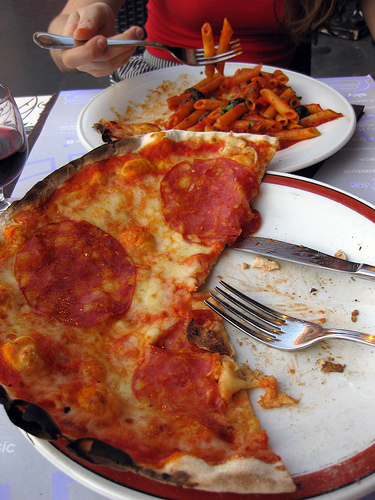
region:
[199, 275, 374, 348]
silver fork by the pizza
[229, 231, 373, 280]
silver knife by the pizza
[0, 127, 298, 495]
pepperoni pizza on the plate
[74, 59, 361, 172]
white plate with pasta on it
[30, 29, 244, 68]
silver fork with pasta on it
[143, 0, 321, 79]
red shirt on the woman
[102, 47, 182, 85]
black and white stripe bottoms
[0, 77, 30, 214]
clear glass of red wine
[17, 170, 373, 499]
red, white and black plate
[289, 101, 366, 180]
black napkin under the white plate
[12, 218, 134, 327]
pepperoni on pizza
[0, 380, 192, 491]
burnt pizza crust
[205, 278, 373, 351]
metal fork on the plate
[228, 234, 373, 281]
metal knife on the plate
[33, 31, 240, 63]
metal fork in woman's hand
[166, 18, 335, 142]
pasta dish on the plate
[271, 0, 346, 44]
woman's brown hair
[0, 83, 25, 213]
red wine in wine glass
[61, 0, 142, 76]
woman's hand holding the fork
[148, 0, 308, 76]
woman wearing a red shirt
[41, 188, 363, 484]
Pizza on a plate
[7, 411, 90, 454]
The crust on the pizza is burnt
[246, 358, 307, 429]
Piece of cheese on the plate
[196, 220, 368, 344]
Fork and knife on the plate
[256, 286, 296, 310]
Sauce on the plate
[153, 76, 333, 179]
Pasta in a bowl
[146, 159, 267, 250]
Pepperoni on top of pizza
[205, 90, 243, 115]
Spices on top of pasta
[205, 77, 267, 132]
Round noodles on plate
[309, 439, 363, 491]
The plate is round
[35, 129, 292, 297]
A partially eaten pizza.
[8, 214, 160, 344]
Pizza with many pepparoni's.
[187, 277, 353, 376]
A silver fork on the plate.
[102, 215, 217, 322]
Mega cheese on the pizza.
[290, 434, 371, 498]
A white plate with a burgandy rim.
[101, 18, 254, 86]
Forking up pasta with sauce.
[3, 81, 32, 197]
Glass of red wine.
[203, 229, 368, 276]
Silver knife on the plate.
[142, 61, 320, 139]
Pasta with tomato sauce.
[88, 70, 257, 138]
A white dish with pasta.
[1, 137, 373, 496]
someone has been eating pizza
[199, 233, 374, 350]
knife and fork used to cut a slice of pizza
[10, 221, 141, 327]
pepperoni slice on a pizza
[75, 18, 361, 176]
this is a plate of rigatoni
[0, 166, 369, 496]
this plate is white with red trim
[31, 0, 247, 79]
this diner holds her fork in her right hand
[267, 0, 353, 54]
diner has long brown hair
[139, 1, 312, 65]
diner wearing a snug red top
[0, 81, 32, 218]
wine has been served with the meal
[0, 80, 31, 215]
diner is drinking red wine